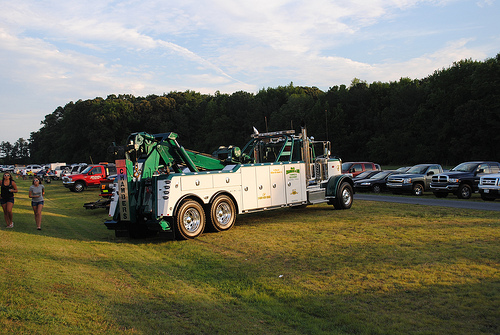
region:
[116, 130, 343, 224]
gren and white tow truck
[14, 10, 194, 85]
white clouds against blue sky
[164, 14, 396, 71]
white clouds against blue sky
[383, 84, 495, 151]
green trees near parking lot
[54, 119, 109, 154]
green trees near parking lot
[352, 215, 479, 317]
short green and brown grass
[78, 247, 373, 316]
short green and brown grass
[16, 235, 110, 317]
short green and brown grass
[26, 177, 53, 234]
young woman running on grass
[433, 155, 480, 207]
black truck parked in lot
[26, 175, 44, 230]
a girl jogging in the grass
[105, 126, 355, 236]
a heavy duty tow truck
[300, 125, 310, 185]
the tow trucks exhaust pipe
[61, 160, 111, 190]
a red emergency vehicle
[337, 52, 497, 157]
a thick forest behind the parked vehicle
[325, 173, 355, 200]
the green fender of the tow truck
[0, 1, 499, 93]
blue sky with white clouds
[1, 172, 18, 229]
a girl wearing black short and top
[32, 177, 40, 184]
a girl wearing white framed sunglasses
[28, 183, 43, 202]
the girl is wearing a grey t-shirt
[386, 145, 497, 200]
There are multiple trucks parked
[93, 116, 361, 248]
Huge tow truck parked on the grass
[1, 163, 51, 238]
Two women walking on the grass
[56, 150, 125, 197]
Red truck with white letters on the door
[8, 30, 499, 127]
Many trees on the background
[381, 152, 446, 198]
Grey truck on the side of the road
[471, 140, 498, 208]
White SUV parked on the side of the road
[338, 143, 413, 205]
Cars parked between trucks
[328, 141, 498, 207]
Vehicles parked parallel to each other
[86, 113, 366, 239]
Big white and green truck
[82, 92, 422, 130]
the forest is dark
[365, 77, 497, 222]
the forest is dark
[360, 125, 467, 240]
the forest is dark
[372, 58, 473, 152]
the forest is dark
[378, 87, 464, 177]
the forest is dark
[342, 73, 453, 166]
the forest is dark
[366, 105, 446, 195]
the forest is dark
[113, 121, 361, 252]
a tow truck in a field.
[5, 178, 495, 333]
a field of lush green grass.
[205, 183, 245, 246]
a wheel on a truck.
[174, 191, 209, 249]
the wheel on the back of a truck.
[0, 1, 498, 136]
a cloudy blue sky.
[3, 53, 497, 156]
a forest of green trees.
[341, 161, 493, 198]
a parking lot filled with cars.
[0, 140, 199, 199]
a parking lot of cars.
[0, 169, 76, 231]
a couple of people wlaking on grass.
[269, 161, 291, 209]
a storage compartment on a truck.